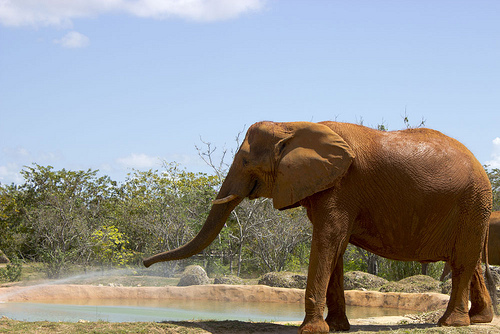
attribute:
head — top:
[141, 119, 291, 268]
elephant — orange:
[246, 120, 498, 296]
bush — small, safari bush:
[26, 186, 91, 278]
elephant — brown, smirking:
[135, 116, 497, 332]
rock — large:
[175, 262, 212, 287]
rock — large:
[211, 272, 246, 286]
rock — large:
[258, 269, 307, 289]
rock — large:
[345, 269, 386, 290]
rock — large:
[381, 273, 443, 295]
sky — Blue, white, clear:
[0, 0, 498, 198]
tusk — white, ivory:
[205, 192, 237, 206]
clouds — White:
[5, 6, 256, 36]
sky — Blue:
[326, 12, 476, 77]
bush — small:
[90, 221, 142, 268]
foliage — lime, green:
[115, 239, 118, 244]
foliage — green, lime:
[107, 234, 112, 239]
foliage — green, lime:
[105, 222, 113, 229]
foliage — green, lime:
[119, 258, 126, 265]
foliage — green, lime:
[90, 230, 97, 235]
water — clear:
[5, 295, 432, 322]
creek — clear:
[69, 280, 168, 325]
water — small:
[7, 302, 304, 322]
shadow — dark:
[164, 320, 304, 332]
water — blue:
[88, 305, 200, 327]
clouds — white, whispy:
[21, 1, 250, 28]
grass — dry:
[2, 312, 499, 333]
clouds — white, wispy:
[95, 102, 186, 192]